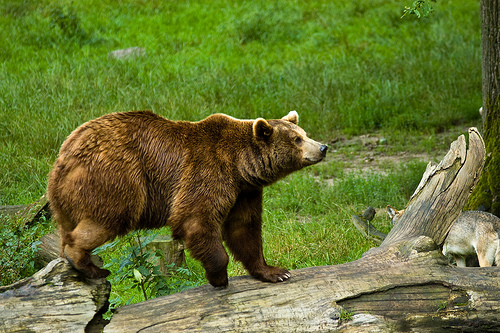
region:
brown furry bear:
[42, 111, 335, 284]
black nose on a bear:
[316, 140, 333, 157]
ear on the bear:
[254, 118, 271, 138]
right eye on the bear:
[295, 136, 305, 143]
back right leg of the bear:
[53, 217, 125, 278]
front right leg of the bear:
[165, 200, 235, 286]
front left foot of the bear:
[251, 264, 301, 281]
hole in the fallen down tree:
[334, 276, 470, 326]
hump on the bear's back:
[204, 109, 231, 120]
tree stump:
[143, 236, 189, 268]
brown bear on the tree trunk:
[10, 55, 326, 272]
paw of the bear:
[250, 248, 297, 283]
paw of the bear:
[209, 264, 235, 292]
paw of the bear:
[64, 251, 96, 277]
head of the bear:
[250, 108, 329, 186]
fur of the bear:
[188, 133, 218, 155]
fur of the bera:
[100, 172, 142, 206]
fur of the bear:
[93, 179, 115, 191]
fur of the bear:
[191, 177, 228, 213]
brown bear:
[20, 78, 320, 263]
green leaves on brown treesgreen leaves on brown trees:
[145, 13, 223, 65]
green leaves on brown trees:
[177, 23, 238, 80]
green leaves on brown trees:
[294, 196, 349, 240]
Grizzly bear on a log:
[45, 103, 330, 293]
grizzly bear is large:
[45, 105, 327, 292]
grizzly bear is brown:
[44, 103, 333, 290]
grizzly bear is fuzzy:
[48, 104, 331, 294]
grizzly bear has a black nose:
[317, 141, 330, 160]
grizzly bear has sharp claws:
[268, 261, 294, 284]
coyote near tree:
[383, 201, 498, 265]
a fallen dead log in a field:
[1, 122, 495, 332]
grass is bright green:
[2, 0, 494, 304]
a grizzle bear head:
[249, 106, 330, 179]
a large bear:
[57, 95, 303, 271]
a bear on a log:
[36, 108, 284, 323]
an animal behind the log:
[426, 196, 492, 261]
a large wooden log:
[16, 200, 492, 315]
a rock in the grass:
[96, 33, 154, 60]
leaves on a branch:
[117, 237, 158, 278]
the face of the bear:
[232, 105, 317, 181]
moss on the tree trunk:
[473, 141, 499, 206]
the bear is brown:
[46, 108, 331, 288]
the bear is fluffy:
[46, 108, 328, 290]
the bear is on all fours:
[47, 109, 327, 292]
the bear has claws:
[46, 110, 329, 290]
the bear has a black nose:
[46, 109, 327, 290]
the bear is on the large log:
[0, 110, 497, 332]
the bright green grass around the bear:
[0, 0, 499, 319]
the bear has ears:
[45, 110, 328, 289]